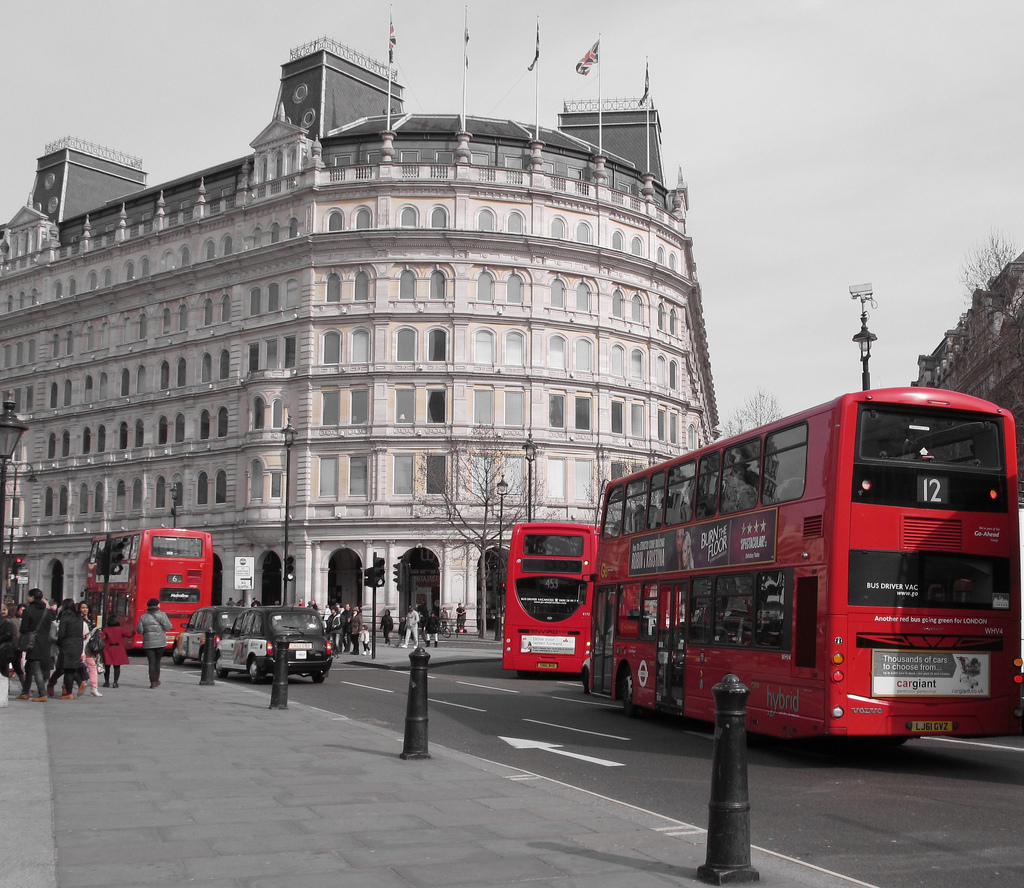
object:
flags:
[389, 7, 397, 63]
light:
[364, 552, 386, 660]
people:
[135, 598, 171, 688]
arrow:
[496, 736, 627, 767]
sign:
[871, 648, 991, 699]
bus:
[581, 387, 1024, 744]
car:
[213, 605, 333, 683]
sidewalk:
[0, 658, 873, 888]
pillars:
[399, 648, 432, 761]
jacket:
[135, 607, 171, 649]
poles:
[528, 20, 541, 142]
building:
[0, 3, 723, 631]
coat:
[99, 626, 135, 666]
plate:
[911, 720, 952, 732]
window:
[429, 328, 448, 362]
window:
[425, 384, 445, 425]